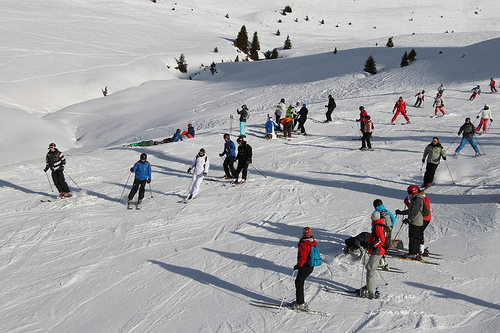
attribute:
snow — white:
[128, 210, 279, 305]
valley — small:
[57, 80, 191, 144]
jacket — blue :
[129, 158, 158, 183]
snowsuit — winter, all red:
[381, 85, 427, 135]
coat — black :
[45, 149, 65, 173]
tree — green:
[232, 22, 251, 59]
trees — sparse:
[193, 15, 304, 55]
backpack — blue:
[302, 237, 322, 265]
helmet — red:
[404, 182, 421, 195]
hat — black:
[396, 94, 403, 104]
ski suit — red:
[386, 94, 413, 126]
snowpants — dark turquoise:
[453, 132, 483, 158]